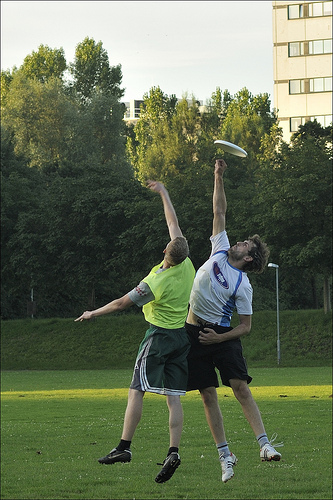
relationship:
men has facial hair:
[185, 124, 288, 492] [223, 248, 243, 261]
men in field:
[69, 139, 289, 492] [4, 364, 329, 497]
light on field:
[0, 382, 330, 400] [0, 360, 332, 497]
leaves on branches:
[0, 29, 330, 180] [20, 51, 311, 170]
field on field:
[0, 360, 332, 497] [4, 364, 329, 497]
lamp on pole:
[264, 260, 279, 269] [273, 261, 283, 366]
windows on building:
[280, 31, 332, 61] [267, 2, 332, 144]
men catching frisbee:
[185, 124, 288, 492] [202, 125, 252, 179]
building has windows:
[258, 3, 332, 171] [280, 31, 332, 61]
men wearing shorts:
[185, 124, 288, 492] [103, 297, 263, 440]